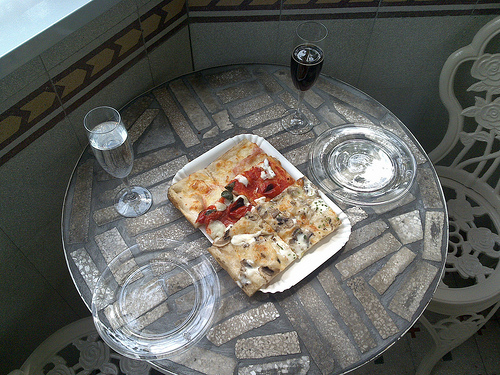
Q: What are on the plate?
A: Square sliced pizza.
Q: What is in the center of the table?
A: A plate of square sliced pizza.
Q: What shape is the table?
A: Round.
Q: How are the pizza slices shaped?
A: Squares.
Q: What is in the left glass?
A: Water.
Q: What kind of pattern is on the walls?
A: Yellow and red arrows.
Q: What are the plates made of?
A: Clear glass.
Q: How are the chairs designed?
A: White wicker pattern.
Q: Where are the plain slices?
A: Left side of pizza tray.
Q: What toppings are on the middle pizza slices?
A: Sun-dried tomatoes, feta, and pesto.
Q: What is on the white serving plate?
A: Square pizza slices.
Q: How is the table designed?
A: Round and gray with brown slats.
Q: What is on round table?
A: Stones.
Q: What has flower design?
A: The chair.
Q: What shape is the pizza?
A: Squared.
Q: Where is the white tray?
A: On table.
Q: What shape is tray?
A: Rectangular.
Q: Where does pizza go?
A: On clear plates.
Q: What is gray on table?
A: The stones.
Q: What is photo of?
A: Food on outdoor table.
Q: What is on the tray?
A: Food.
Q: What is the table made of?
A: Concrete and grout.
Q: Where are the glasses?
A: On the table.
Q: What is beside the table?
A: A chair.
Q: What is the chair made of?
A: Metal.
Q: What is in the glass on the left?
A: A liquid.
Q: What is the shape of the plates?
A: Round.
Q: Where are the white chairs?
A: Next to the table.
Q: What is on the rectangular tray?
A: Pizza.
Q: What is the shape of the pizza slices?
A: Square.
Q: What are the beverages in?
A: Wine glasses.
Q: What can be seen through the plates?
A: The table.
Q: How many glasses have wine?
A: 1.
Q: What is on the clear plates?
A: Nothing.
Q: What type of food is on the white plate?
A: Pizza.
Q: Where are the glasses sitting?
A: Table.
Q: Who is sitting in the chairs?
A: No one.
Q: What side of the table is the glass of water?
A: Left side.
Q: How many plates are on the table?
A: Two.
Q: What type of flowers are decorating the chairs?
A: Roses.